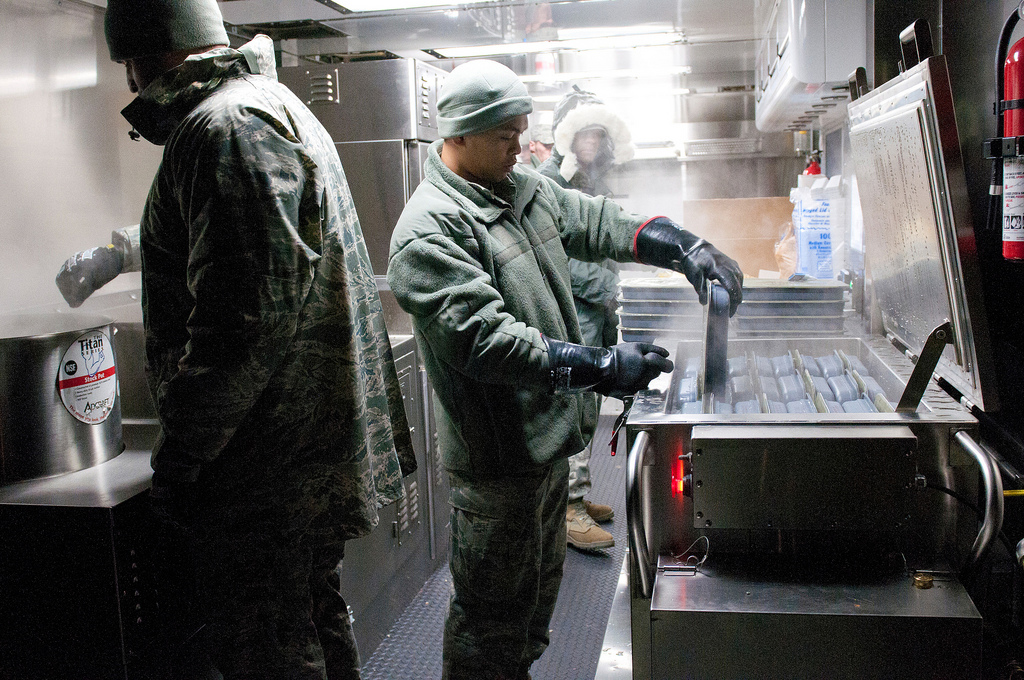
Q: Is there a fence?
A: No, there are no fences.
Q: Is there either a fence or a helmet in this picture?
A: No, there are no fences or helmets.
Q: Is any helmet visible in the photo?
A: No, there are no helmets.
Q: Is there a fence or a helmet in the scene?
A: No, there are no helmets or fences.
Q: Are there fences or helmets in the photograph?
A: No, there are no helmets or fences.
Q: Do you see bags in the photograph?
A: No, there are no bags.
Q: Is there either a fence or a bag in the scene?
A: No, there are no bags or fences.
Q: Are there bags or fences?
A: No, there are no bags or fences.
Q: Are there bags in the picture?
A: No, there are no bags.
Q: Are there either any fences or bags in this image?
A: No, there are no bags or fences.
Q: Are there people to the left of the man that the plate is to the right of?
A: Yes, there is a person to the left of the man.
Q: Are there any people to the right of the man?
A: No, the person is to the left of the man.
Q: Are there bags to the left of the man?
A: No, there is a person to the left of the man.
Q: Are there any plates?
A: Yes, there is a plate.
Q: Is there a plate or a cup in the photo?
A: Yes, there is a plate.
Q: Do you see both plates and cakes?
A: No, there is a plate but no cakes.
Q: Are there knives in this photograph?
A: No, there are no knives.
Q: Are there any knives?
A: No, there are no knives.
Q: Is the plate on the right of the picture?
A: Yes, the plate is on the right of the image.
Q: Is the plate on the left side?
A: No, the plate is on the right of the image.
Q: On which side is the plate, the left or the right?
A: The plate is on the right of the image.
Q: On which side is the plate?
A: The plate is on the right of the image.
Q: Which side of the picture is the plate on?
A: The plate is on the right of the image.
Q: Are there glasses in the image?
A: No, there are no glasses.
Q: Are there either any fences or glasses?
A: No, there are no glasses or fences.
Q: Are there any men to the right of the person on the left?
A: Yes, there is a man to the right of the person.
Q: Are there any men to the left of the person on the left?
A: No, the man is to the right of the person.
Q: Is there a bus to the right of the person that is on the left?
A: No, there is a man to the right of the person.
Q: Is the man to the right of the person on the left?
A: Yes, the man is to the right of the person.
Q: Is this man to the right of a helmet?
A: No, the man is to the right of the person.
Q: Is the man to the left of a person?
A: No, the man is to the right of a person.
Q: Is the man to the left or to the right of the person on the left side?
A: The man is to the right of the person.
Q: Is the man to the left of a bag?
A: No, the man is to the left of a plate.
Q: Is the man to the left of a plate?
A: Yes, the man is to the left of a plate.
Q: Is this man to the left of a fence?
A: No, the man is to the left of a plate.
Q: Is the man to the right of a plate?
A: No, the man is to the left of a plate.